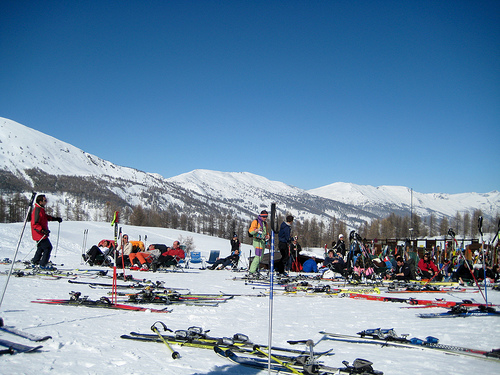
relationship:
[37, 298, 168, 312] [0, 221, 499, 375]
ski on ground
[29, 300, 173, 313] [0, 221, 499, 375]
ski on ground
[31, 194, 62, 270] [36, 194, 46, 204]
man has hair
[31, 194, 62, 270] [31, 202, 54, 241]
man wears a jacket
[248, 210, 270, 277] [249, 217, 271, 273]
person wears an outfit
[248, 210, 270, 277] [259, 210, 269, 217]
person wears a hat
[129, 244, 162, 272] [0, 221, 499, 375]
person laying on ground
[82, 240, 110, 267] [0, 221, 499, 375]
person laying on ground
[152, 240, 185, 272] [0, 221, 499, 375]
person laying on ground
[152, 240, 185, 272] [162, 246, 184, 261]
person wearing a jacket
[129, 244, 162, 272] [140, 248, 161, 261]
person wearing a jacket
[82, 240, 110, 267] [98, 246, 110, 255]
person wearing a jacket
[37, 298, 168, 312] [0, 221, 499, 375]
ski laying on ground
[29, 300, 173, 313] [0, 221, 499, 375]
ski laying on ground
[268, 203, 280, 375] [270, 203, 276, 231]
ski pole has a handle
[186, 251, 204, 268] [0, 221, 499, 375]
chair stands on ground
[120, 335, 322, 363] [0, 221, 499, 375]
ski on ground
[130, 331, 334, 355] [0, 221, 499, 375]
ski on ground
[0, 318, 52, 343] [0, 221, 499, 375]
ski on ground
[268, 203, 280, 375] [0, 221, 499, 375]
ski pole on ground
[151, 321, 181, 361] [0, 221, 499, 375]
ski pole on ground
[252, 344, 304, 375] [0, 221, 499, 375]
ski pole on ground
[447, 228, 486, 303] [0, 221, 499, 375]
ski pole on ground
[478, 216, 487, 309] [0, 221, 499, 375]
ski pole on ground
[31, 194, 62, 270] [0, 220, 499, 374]
man in skiing area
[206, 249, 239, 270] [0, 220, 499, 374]
man in skiing area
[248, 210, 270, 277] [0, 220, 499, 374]
person in skiing area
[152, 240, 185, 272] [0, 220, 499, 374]
person in skiing area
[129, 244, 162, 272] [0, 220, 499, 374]
person in skiing area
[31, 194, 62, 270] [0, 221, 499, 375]
man on ground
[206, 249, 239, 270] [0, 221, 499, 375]
man on ground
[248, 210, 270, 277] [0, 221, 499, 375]
person on ground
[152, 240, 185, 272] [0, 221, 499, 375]
person on ground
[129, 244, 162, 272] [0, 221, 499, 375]
person on ground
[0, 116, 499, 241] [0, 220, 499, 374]
mountain range behind skiing area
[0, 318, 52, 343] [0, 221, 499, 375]
ski sitting on ground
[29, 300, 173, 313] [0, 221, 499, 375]
ski sitting on ground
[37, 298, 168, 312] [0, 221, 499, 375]
ski sitting on ground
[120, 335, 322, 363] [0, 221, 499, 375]
ski sitting on ground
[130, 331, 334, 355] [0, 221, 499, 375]
ski sitting on ground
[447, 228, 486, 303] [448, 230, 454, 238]
ski pole has a handle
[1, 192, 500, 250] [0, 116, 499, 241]
wooded area in front of mountain range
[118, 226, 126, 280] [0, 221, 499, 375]
ski pole on ground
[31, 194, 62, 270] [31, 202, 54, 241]
man in a jacket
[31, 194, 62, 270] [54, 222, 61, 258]
man holds a ski pole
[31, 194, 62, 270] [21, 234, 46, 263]
man holds a ski pole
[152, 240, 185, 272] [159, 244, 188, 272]
person lounges on a chair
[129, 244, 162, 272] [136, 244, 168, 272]
person lounges on a chair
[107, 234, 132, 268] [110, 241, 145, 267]
person lounges on a chair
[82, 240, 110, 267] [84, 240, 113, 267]
person lounges on a chair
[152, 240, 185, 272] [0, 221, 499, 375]
person sitting on ground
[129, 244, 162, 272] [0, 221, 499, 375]
person sitting on ground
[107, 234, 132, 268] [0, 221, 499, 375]
person sitting on ground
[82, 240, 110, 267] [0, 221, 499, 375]
person sitting on ground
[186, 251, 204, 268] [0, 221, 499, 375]
chair on ground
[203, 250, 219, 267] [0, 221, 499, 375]
chair on ground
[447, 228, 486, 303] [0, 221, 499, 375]
ski pole propped in ground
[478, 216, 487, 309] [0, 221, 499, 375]
ski pole propped in ground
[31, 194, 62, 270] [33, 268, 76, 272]
man wearing a ski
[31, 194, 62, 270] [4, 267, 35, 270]
man wearing a ski